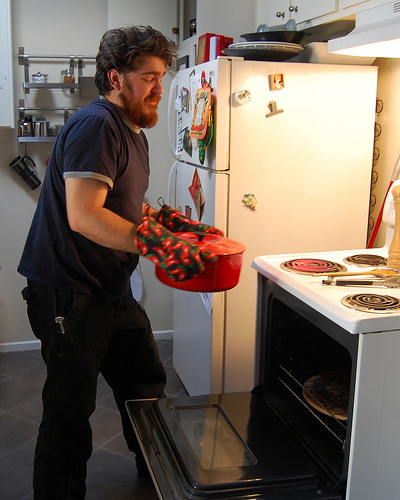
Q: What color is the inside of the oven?
A: Black.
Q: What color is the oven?
A: White.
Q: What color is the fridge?
A: White.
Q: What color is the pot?
A: Red.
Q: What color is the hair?
A: Brown.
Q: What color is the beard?
A: Red.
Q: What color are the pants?
A: Black.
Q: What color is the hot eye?
A: Red.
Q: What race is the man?
A: White.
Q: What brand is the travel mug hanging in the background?
A: Contigo.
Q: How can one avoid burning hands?
A: Use oven mitts.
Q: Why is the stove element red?
A: It is hot.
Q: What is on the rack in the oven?
A: A baking stone.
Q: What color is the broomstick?
A: Red.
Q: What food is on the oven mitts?
A: Chilis.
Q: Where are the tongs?
A: On the stove.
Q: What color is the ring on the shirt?
A: Grey.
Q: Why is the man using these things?
A: To cook.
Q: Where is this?
A: Kitchen.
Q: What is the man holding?
A: A pot.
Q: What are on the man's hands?
A: Hot pad mitts.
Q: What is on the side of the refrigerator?
A: Magnets.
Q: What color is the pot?
A: Red.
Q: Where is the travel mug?
A: Hanging on the back wall.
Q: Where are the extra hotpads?
A: On the refrigerator.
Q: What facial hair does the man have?
A: Beard and mustache.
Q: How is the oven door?
A: Open.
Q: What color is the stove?
A: White.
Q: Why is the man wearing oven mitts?
A: Safety.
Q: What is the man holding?
A: A pot.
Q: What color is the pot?
A: Red.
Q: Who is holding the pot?
A: The man.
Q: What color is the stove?
A: White.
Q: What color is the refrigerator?
A: White.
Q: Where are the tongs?
A: On top of the stove.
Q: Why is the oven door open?
A: To get the food.